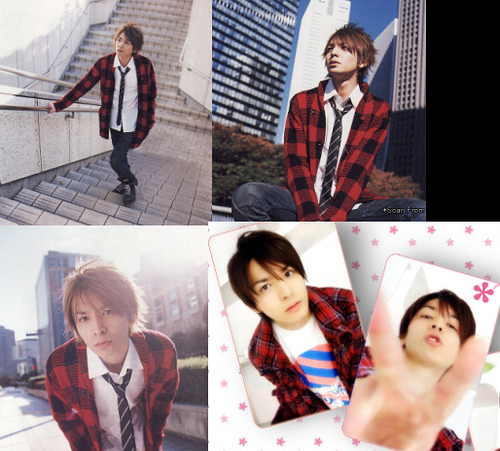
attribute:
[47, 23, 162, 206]
person — climbing the stairs, young, standing on steps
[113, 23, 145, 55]
hair — dark, brown, messy, long, dark brown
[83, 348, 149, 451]
shirt — white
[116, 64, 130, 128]
tie — long, skinny, old new wave, dark, black, striped, white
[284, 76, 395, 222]
shirt — plaid, red, black, long sleeved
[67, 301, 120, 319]
eyebrows — nicely shaped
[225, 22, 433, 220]
man — seated, sitting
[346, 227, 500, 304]
stars — pink, little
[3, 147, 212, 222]
stairs — gray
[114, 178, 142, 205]
shoes — dark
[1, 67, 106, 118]
rail — metal, silver